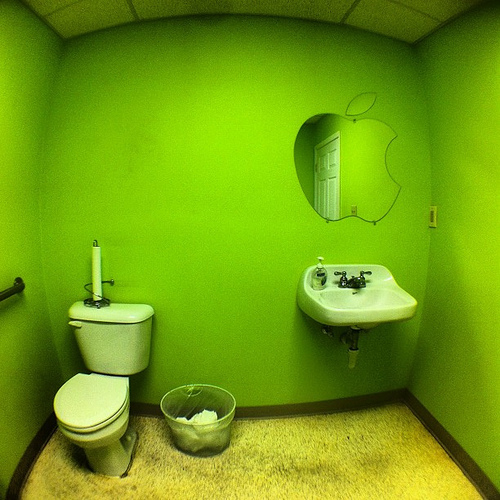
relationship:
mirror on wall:
[281, 81, 407, 234] [61, 20, 414, 405]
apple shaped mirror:
[281, 80, 417, 233] [281, 81, 407, 234]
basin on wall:
[297, 261, 418, 368] [61, 20, 414, 405]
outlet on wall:
[422, 198, 443, 232] [408, 8, 500, 454]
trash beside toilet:
[167, 398, 226, 445] [39, 283, 163, 483]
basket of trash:
[157, 381, 238, 455] [167, 398, 226, 445]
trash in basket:
[167, 398, 226, 445] [157, 381, 238, 455]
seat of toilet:
[48, 367, 144, 443] [39, 283, 163, 483]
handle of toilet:
[67, 318, 91, 332] [39, 283, 163, 483]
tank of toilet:
[59, 293, 160, 381] [39, 283, 163, 483]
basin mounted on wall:
[293, 250, 424, 373] [61, 20, 414, 405]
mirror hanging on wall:
[281, 81, 407, 234] [61, 20, 414, 405]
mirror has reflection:
[281, 81, 407, 234] [304, 131, 349, 210]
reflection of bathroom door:
[304, 131, 349, 210] [312, 132, 352, 216]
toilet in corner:
[39, 283, 163, 483] [3, 230, 192, 499]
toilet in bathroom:
[39, 283, 163, 483] [1, 4, 499, 483]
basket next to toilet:
[154, 367, 248, 461] [39, 283, 163, 483]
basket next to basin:
[154, 367, 248, 461] [293, 250, 424, 373]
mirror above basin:
[281, 81, 407, 234] [293, 250, 424, 373]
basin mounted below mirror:
[293, 250, 424, 373] [281, 81, 407, 234]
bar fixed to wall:
[0, 270, 30, 314] [0, 4, 79, 460]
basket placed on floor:
[154, 367, 248, 461] [53, 380, 477, 498]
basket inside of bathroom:
[157, 381, 238, 455] [1, 4, 499, 483]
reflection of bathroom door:
[304, 131, 349, 210] [312, 132, 352, 231]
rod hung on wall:
[0, 268, 40, 312] [0, 4, 79, 460]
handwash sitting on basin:
[311, 256, 328, 290] [297, 261, 418, 368]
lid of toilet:
[42, 289, 169, 340] [39, 283, 163, 483]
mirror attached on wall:
[281, 81, 407, 234] [61, 20, 414, 405]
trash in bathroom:
[167, 398, 226, 445] [1, 4, 499, 483]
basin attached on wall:
[297, 261, 418, 368] [61, 20, 414, 405]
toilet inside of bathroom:
[39, 283, 163, 483] [1, 4, 499, 483]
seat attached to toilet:
[48, 367, 144, 443] [39, 283, 163, 483]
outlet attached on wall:
[429, 203, 439, 227] [408, 8, 500, 454]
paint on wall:
[61, 10, 424, 377] [61, 20, 414, 405]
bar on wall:
[0, 270, 30, 314] [61, 20, 414, 405]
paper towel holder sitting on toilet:
[78, 230, 116, 313] [40, 212, 156, 467]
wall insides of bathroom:
[61, 20, 414, 405] [1, 4, 499, 483]